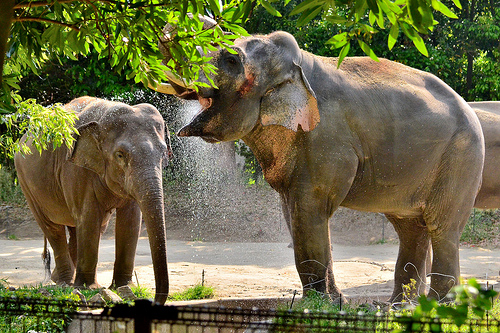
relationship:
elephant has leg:
[15, 96, 171, 303] [71, 197, 111, 291]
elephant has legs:
[15, 96, 171, 303] [27, 195, 80, 283]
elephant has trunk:
[15, 96, 171, 303] [125, 170, 172, 304]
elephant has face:
[15, 96, 171, 303] [95, 103, 170, 200]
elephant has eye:
[123, 12, 486, 311] [222, 52, 243, 69]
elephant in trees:
[15, 96, 171, 303] [0, 1, 247, 169]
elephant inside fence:
[7, 95, 170, 303] [2, 299, 500, 332]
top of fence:
[0, 295, 499, 322] [2, 295, 500, 332]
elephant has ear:
[15, 96, 171, 303] [66, 123, 107, 176]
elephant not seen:
[469, 99, 500, 209] [460, 60, 500, 305]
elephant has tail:
[15, 96, 171, 303] [41, 235, 54, 277]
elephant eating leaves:
[123, 12, 486, 311] [118, 29, 179, 90]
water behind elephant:
[176, 98, 243, 238] [7, 95, 170, 303]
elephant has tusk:
[123, 12, 486, 311] [139, 60, 197, 98]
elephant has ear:
[123, 12, 486, 311] [259, 64, 324, 133]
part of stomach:
[348, 197, 367, 206] [338, 173, 432, 216]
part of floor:
[213, 247, 237, 273] [0, 232, 499, 313]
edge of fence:
[47, 311, 63, 323] [2, 295, 500, 332]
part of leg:
[82, 234, 96, 250] [71, 197, 111, 291]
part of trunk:
[149, 197, 158, 207] [125, 170, 172, 304]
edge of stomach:
[391, 193, 418, 214] [338, 173, 432, 216]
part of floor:
[186, 268, 197, 279] [0, 229, 499, 313]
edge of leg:
[95, 246, 100, 257] [71, 197, 111, 291]